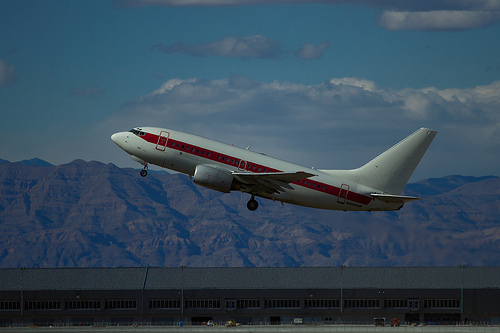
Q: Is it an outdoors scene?
A: Yes, it is outdoors.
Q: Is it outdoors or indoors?
A: It is outdoors.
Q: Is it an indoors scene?
A: No, it is outdoors.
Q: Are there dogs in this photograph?
A: No, there are no dogs.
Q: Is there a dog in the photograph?
A: No, there are no dogs.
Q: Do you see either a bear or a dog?
A: No, there are no dogs or bears.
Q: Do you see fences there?
A: No, there are no fences.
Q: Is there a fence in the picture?
A: No, there are no fences.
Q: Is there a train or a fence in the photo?
A: No, there are no fences or trains.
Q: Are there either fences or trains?
A: No, there are no fences or trains.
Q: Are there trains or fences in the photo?
A: No, there are no fences or trains.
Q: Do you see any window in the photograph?
A: Yes, there are windows.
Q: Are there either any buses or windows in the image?
A: Yes, there are windows.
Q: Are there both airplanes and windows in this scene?
A: Yes, there are both windows and an airplane.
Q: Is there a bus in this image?
A: No, there are no buses.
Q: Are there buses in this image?
A: No, there are no buses.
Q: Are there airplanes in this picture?
A: Yes, there is an airplane.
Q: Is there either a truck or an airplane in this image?
A: Yes, there is an airplane.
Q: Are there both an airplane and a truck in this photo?
A: No, there is an airplane but no trucks.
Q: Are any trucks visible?
A: No, there are no trucks.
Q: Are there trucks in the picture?
A: No, there are no trucks.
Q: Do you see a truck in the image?
A: No, there are no trucks.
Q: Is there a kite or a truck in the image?
A: No, there are no trucks or kites.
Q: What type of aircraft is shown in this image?
A: The aircraft is an airplane.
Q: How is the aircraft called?
A: The aircraft is an airplane.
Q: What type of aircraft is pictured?
A: The aircraft is an airplane.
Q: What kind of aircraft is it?
A: The aircraft is an airplane.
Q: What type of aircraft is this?
A: This is an airplane.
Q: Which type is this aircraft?
A: This is an airplane.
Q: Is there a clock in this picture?
A: No, there are no clocks.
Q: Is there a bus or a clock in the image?
A: No, there are no clocks or buses.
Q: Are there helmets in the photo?
A: No, there are no helmets.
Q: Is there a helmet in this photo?
A: No, there are no helmets.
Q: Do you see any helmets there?
A: No, there are no helmets.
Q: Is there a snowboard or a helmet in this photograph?
A: No, there are no helmets or snowboards.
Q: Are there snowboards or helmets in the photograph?
A: No, there are no helmets or snowboards.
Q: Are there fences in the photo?
A: No, there are no fences.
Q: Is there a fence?
A: No, there are no fences.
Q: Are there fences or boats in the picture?
A: No, there are no fences or boats.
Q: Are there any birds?
A: No, there are no birds.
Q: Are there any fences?
A: No, there are no fences.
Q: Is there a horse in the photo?
A: No, there are no horses.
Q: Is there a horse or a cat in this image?
A: No, there are no horses or cats.